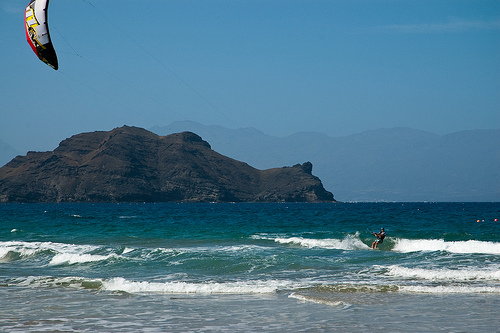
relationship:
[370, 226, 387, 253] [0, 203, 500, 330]
man in water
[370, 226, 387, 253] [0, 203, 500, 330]
man diving in water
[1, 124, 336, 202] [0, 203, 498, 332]
mountain in water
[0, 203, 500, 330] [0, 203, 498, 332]
water in water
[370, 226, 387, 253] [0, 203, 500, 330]
man leaning back over water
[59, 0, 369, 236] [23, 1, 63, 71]
cables of parafoil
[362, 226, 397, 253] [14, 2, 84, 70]
man with parachute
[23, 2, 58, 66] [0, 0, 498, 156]
parafoil in sky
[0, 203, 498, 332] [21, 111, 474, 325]
water coming out to earth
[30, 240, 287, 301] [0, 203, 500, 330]
sea foam on water